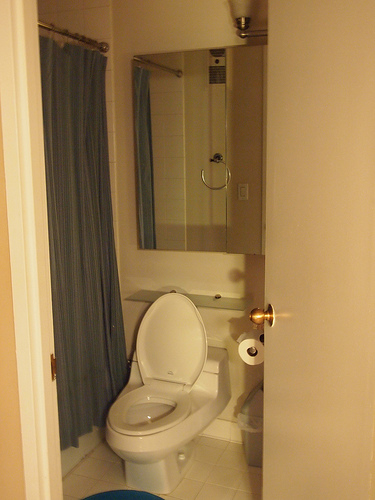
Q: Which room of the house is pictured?
A: It is a bathroom.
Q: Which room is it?
A: It is a bathroom.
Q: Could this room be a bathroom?
A: Yes, it is a bathroom.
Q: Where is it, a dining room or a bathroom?
A: It is a bathroom.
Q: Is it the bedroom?
A: No, it is the bathroom.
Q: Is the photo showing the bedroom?
A: No, the picture is showing the bathroom.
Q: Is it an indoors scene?
A: Yes, it is indoors.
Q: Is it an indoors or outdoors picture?
A: It is indoors.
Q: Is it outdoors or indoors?
A: It is indoors.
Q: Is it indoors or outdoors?
A: It is indoors.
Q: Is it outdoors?
A: No, it is indoors.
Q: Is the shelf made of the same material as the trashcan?
A: No, the shelf is made of glass and the trashcan is made of metal.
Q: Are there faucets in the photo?
A: No, there are no faucets.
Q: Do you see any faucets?
A: No, there are no faucets.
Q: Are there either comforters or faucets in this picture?
A: No, there are no faucets or comforters.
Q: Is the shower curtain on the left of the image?
A: Yes, the shower curtain is on the left of the image.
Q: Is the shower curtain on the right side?
A: No, the shower curtain is on the left of the image.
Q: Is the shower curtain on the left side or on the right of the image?
A: The shower curtain is on the left of the image.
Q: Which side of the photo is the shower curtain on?
A: The shower curtain is on the left of the image.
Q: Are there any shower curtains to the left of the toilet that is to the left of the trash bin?
A: Yes, there is a shower curtain to the left of the toilet.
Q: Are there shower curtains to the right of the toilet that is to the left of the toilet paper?
A: No, the shower curtain is to the left of the toilet.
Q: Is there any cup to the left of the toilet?
A: No, there is a shower curtain to the left of the toilet.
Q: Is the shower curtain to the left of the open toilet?
A: Yes, the shower curtain is to the left of the toilet.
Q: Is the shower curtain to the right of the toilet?
A: No, the shower curtain is to the left of the toilet.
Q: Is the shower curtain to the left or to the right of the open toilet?
A: The shower curtain is to the left of the toilet.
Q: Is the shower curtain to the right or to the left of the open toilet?
A: The shower curtain is to the left of the toilet.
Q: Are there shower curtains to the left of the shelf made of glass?
A: Yes, there is a shower curtain to the left of the shelf.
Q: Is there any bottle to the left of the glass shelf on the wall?
A: No, there is a shower curtain to the left of the shelf.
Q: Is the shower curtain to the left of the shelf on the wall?
A: Yes, the shower curtain is to the left of the shelf.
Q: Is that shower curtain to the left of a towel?
A: No, the shower curtain is to the left of the shelf.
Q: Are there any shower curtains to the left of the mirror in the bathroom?
A: Yes, there is a shower curtain to the left of the mirror.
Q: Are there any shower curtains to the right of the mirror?
A: No, the shower curtain is to the left of the mirror.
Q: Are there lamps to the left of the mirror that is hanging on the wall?
A: No, there is a shower curtain to the left of the mirror.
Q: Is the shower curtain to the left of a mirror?
A: Yes, the shower curtain is to the left of a mirror.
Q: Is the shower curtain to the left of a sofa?
A: No, the shower curtain is to the left of a mirror.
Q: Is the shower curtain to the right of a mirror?
A: No, the shower curtain is to the left of a mirror.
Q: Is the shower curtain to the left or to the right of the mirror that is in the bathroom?
A: The shower curtain is to the left of the mirror.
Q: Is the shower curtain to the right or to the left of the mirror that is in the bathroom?
A: The shower curtain is to the left of the mirror.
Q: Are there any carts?
A: No, there are no carts.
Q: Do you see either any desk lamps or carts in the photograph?
A: No, there are no carts or desk lamps.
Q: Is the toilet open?
A: Yes, the toilet is open.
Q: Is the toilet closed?
A: No, the toilet is open.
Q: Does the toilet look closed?
A: No, the toilet is open.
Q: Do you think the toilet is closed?
A: No, the toilet is open.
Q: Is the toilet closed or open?
A: The toilet is open.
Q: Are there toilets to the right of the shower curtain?
A: Yes, there is a toilet to the right of the shower curtain.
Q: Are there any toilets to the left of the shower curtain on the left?
A: No, the toilet is to the right of the shower curtain.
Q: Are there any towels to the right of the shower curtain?
A: No, there is a toilet to the right of the shower curtain.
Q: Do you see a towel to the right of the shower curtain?
A: No, there is a toilet to the right of the shower curtain.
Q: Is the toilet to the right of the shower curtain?
A: Yes, the toilet is to the right of the shower curtain.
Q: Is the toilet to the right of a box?
A: No, the toilet is to the right of the shower curtain.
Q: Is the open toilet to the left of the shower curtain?
A: No, the toilet is to the right of the shower curtain.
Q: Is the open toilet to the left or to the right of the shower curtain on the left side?
A: The toilet is to the right of the shower curtain.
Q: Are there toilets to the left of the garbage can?
A: Yes, there is a toilet to the left of the garbage can.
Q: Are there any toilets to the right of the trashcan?
A: No, the toilet is to the left of the trashcan.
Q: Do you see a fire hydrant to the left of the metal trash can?
A: No, there is a toilet to the left of the garbage bin.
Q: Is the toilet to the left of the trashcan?
A: Yes, the toilet is to the left of the trashcan.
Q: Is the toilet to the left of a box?
A: No, the toilet is to the left of the trashcan.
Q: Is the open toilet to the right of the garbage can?
A: No, the toilet is to the left of the garbage can.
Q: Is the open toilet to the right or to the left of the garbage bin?
A: The toilet is to the left of the garbage bin.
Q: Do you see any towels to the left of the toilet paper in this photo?
A: No, there is a toilet to the left of the toilet paper.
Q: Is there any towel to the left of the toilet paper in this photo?
A: No, there is a toilet to the left of the toilet paper.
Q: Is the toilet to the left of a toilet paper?
A: Yes, the toilet is to the left of a toilet paper.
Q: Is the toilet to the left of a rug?
A: No, the toilet is to the left of a toilet paper.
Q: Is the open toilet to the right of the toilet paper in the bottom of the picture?
A: No, the toilet is to the left of the toilet paper.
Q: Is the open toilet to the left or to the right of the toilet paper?
A: The toilet is to the left of the toilet paper.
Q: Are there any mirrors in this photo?
A: Yes, there is a mirror.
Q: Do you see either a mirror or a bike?
A: Yes, there is a mirror.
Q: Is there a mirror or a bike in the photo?
A: Yes, there is a mirror.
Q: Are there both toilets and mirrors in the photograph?
A: Yes, there are both a mirror and a toilet.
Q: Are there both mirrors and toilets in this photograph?
A: Yes, there are both a mirror and a toilet.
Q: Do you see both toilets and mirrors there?
A: Yes, there are both a mirror and a toilet.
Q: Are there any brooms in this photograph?
A: No, there are no brooms.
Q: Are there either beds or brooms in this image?
A: No, there are no brooms or beds.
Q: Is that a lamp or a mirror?
A: That is a mirror.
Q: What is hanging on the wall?
A: The mirror is hanging on the wall.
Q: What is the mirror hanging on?
A: The mirror is hanging on the wall.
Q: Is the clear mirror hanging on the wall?
A: Yes, the mirror is hanging on the wall.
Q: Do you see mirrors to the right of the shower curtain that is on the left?
A: Yes, there is a mirror to the right of the shower curtain.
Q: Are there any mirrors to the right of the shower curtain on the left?
A: Yes, there is a mirror to the right of the shower curtain.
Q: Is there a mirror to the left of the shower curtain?
A: No, the mirror is to the right of the shower curtain.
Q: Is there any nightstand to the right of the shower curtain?
A: No, there is a mirror to the right of the shower curtain.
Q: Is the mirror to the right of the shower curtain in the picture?
A: Yes, the mirror is to the right of the shower curtain.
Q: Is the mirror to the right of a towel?
A: No, the mirror is to the right of the shower curtain.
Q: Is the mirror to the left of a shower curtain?
A: No, the mirror is to the right of a shower curtain.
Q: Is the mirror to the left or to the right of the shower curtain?
A: The mirror is to the right of the shower curtain.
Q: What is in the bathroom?
A: The mirror is in the bathroom.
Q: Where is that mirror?
A: The mirror is in the bathroom.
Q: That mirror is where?
A: The mirror is in the bathroom.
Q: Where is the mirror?
A: The mirror is in the bathroom.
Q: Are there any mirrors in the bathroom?
A: Yes, there is a mirror in the bathroom.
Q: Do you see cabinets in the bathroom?
A: No, there is a mirror in the bathroom.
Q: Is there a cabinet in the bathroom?
A: No, there is a mirror in the bathroom.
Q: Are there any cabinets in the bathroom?
A: No, there is a mirror in the bathroom.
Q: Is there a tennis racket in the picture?
A: No, there are no rackets.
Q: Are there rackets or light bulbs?
A: No, there are no rackets or light bulbs.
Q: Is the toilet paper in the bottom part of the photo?
A: Yes, the toilet paper is in the bottom of the image.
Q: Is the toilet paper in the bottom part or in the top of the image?
A: The toilet paper is in the bottom of the image.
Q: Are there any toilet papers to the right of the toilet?
A: Yes, there is a toilet paper to the right of the toilet.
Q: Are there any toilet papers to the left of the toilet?
A: No, the toilet paper is to the right of the toilet.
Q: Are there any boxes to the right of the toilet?
A: No, there is a toilet paper to the right of the toilet.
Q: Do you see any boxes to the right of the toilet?
A: No, there is a toilet paper to the right of the toilet.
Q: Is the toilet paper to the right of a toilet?
A: Yes, the toilet paper is to the right of a toilet.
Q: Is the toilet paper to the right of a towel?
A: No, the toilet paper is to the right of a toilet.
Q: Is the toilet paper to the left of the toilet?
A: No, the toilet paper is to the right of the toilet.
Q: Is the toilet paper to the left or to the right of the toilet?
A: The toilet paper is to the right of the toilet.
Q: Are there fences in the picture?
A: No, there are no fences.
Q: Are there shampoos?
A: No, there are no shampoos.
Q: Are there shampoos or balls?
A: No, there are no shampoos or balls.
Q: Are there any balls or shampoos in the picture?
A: No, there are no shampoos or balls.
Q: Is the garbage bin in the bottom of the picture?
A: Yes, the garbage bin is in the bottom of the image.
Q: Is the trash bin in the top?
A: No, the trash bin is in the bottom of the image.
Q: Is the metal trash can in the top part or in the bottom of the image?
A: The trash can is in the bottom of the image.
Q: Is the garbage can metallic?
A: Yes, the garbage can is metallic.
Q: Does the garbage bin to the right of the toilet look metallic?
A: Yes, the trash can is metallic.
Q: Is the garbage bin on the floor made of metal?
A: Yes, the trash can is made of metal.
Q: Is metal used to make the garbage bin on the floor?
A: Yes, the trash can is made of metal.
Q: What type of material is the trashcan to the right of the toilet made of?
A: The garbage bin is made of metal.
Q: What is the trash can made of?
A: The garbage bin is made of metal.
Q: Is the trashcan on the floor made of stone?
A: No, the garbage bin is made of metal.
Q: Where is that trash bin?
A: The trash bin is on the floor.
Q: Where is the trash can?
A: The trash bin is on the floor.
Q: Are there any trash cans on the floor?
A: Yes, there is a trash can on the floor.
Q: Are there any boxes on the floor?
A: No, there is a trash can on the floor.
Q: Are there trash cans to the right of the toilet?
A: Yes, there is a trash can to the right of the toilet.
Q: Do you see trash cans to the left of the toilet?
A: No, the trash can is to the right of the toilet.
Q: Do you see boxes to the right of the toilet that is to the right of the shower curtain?
A: No, there is a trash can to the right of the toilet.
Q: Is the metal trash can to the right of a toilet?
A: Yes, the trash can is to the right of a toilet.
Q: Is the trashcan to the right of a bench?
A: No, the trashcan is to the right of a toilet.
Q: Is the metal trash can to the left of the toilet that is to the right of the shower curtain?
A: No, the trash bin is to the right of the toilet.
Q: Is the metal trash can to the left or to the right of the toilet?
A: The trash bin is to the right of the toilet.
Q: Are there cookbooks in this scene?
A: No, there are no cookbooks.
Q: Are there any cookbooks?
A: No, there are no cookbooks.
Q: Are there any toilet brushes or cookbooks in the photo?
A: No, there are no cookbooks or toilet brushes.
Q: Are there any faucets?
A: No, there are no faucets.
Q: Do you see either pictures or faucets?
A: No, there are no faucets or pictures.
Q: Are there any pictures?
A: No, there are no pictures.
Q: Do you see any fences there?
A: No, there are no fences.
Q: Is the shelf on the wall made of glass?
A: Yes, the shelf is made of glass.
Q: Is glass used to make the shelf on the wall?
A: Yes, the shelf is made of glass.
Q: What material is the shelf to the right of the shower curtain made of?
A: The shelf is made of glass.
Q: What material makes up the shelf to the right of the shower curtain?
A: The shelf is made of glass.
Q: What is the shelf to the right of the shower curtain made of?
A: The shelf is made of glass.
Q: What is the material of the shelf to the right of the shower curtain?
A: The shelf is made of glass.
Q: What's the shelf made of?
A: The shelf is made of glass.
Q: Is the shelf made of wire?
A: No, the shelf is made of glass.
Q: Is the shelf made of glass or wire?
A: The shelf is made of glass.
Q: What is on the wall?
A: The shelf is on the wall.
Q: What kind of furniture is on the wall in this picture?
A: The piece of furniture is a shelf.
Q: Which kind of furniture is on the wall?
A: The piece of furniture is a shelf.